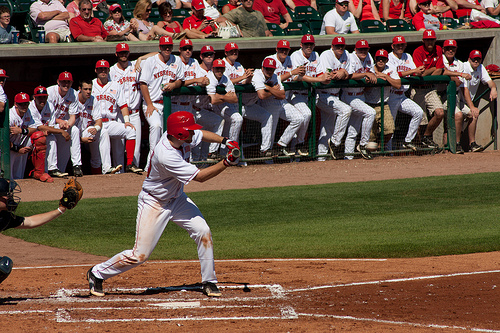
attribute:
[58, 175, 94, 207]
catchers mitt — brown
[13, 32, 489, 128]
players — lined up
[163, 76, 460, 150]
fence — green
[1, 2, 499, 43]
audience — watching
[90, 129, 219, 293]
uniform — white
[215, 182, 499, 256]
grass — green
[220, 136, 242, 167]
gloves — black, red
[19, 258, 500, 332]
dirt — brown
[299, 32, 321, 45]
hat — red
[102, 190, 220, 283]
pants — dirty, white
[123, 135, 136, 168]
socks — red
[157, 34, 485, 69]
hats — red, white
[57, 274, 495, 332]
lines — white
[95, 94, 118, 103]
lettering — red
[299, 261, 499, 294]
third base line — white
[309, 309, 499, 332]
first base line — white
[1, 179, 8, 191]
hat — black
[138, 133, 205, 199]
jersey — white